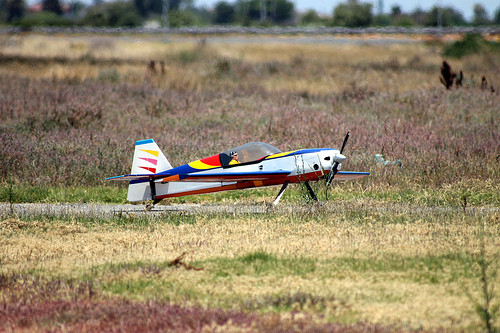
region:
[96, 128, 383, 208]
a small airplane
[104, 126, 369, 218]
airplane sitting on the ground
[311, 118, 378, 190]
propeller on the front of the plane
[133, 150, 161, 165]
pink stripe on the tail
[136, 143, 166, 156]
yellow stripe on the tail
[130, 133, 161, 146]
top of the tail is blue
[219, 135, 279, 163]
windows around the cockpit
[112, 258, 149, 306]
green grass on ground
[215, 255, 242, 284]
green grass on ground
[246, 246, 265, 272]
green grass on ground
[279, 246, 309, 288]
green grass on ground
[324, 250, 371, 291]
green grass on ground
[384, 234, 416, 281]
green grass on ground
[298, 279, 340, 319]
green grass on ground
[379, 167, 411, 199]
green grass on ground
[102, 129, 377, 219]
Aeroplane on the ground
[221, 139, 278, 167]
Pilot in a cockpit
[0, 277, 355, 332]
Short plants of violet color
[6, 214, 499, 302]
Short brown grass cover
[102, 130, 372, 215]
Plane of multiple colors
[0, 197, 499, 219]
Grey length of runway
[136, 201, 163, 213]
Landing gear on the ground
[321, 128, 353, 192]
Black colored propeller on the tip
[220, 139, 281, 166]
Curved glass of the cockpit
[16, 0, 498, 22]
Hazy blue sky background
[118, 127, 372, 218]
the plane has landed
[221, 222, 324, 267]
floor is grey in color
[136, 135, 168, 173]
tail has red yellow and blu stripes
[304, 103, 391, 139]
flowers are grey in color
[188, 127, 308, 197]
young man is seated o n th plane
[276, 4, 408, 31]
trees far awy from the view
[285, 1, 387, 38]
trees are green in color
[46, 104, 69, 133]
THIS IS DRY GRASS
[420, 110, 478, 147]
THIS IS DRY GRASS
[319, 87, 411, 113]
THIS IS DRY GRASS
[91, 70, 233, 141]
THIS IS DRY GRASS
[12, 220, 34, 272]
THIS IS DRY GRASS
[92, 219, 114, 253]
THIS IS DRY GRASS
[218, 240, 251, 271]
THIS IS DRY GRASS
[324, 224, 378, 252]
THIS IS DRY GRASS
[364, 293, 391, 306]
THIS IS DRY GRASS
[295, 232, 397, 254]
THIS IS DRY GRASS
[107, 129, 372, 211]
a colorful airplane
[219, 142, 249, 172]
a man sitting in the airplane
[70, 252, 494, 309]
a patch of grass in front of airplane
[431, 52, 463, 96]
a pine tree in the right field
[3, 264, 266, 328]
purple grass in the foreground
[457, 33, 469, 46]
green leaves on the tree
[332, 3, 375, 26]
green leaves on the tree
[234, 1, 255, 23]
green leaves on the tree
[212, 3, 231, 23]
green leaves on the tree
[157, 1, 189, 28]
green leaves on the tree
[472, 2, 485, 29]
green leaves on the tree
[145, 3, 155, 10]
green leaves on the tree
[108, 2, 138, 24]
green leaves on the tree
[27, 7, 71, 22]
green leaves on the tree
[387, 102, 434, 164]
green grass around the airplane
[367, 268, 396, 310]
green grass around the airplane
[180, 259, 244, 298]
green grass around the airplane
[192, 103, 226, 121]
green grass around the airplane